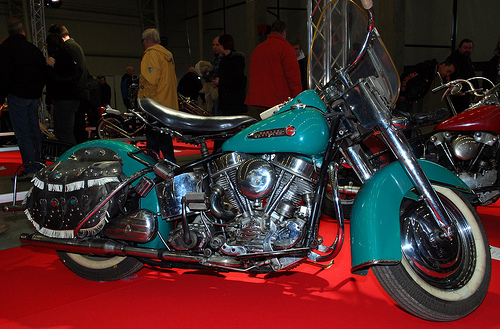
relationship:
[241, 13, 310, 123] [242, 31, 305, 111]
man wears jacket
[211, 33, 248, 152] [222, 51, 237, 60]
man has neck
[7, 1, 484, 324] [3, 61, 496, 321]
motorcycle on display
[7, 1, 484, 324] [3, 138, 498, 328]
motorcycle parked on carpet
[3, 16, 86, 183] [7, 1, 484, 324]
men standing behind motorcycle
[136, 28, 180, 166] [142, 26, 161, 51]
man has hair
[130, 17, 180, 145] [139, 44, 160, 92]
man has arm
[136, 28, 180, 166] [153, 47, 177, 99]
man has back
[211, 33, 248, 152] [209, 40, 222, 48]
man has eyes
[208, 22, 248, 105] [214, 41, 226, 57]
man has nose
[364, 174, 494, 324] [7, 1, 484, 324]
front tire of motorcycle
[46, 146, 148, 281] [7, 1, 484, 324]
back tire of motorcycle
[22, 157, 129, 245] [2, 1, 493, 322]
saddle bag on rear of motorcycle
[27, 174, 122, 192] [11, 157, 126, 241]
fringe on saddle bag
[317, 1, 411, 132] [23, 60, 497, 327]
windshield on motorcycle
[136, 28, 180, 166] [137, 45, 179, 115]
man wearing jacket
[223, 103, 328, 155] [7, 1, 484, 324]
gas tank on a motorcycle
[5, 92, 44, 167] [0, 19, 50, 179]
jean pants on a man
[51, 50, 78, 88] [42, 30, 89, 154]
purse on a woman